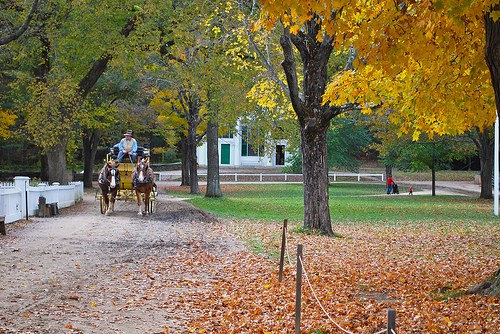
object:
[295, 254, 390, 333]
chain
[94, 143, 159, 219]
carraige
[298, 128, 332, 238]
trunk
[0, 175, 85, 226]
picket fence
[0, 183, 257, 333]
road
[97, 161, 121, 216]
horse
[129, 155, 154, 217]
horse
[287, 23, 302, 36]
leaves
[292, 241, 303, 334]
pole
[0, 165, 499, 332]
ground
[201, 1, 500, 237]
tree